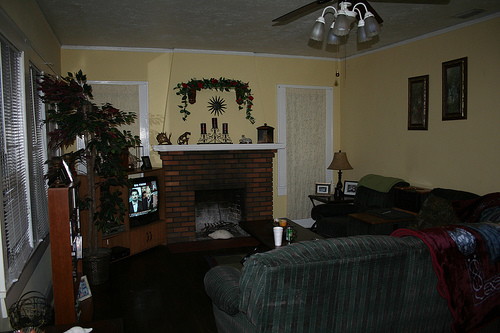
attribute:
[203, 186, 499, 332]
couch — green striped, lined, blue, striped velour, striped, grayish blue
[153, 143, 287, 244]
fire place — brick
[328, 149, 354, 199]
lamp — small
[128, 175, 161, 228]
television — off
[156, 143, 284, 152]
mantel — white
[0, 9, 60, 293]
window — white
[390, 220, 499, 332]
blanket — red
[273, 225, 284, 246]
cup — white, styrofoam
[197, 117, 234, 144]
candles — a set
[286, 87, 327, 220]
curtain — beige, long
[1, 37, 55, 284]
blinds — venitions blinds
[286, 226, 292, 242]
soda can — green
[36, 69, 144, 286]
tee — tall, potted